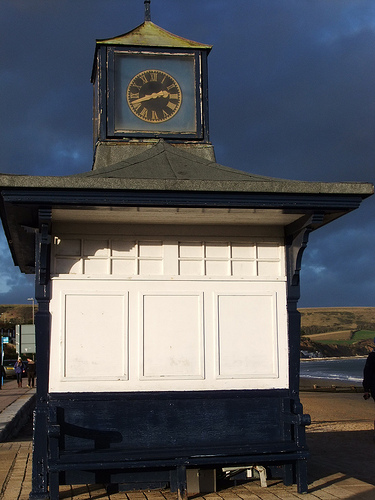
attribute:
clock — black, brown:
[108, 56, 196, 133]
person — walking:
[15, 356, 24, 387]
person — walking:
[25, 356, 37, 390]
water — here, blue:
[301, 353, 374, 383]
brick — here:
[3, 484, 24, 499]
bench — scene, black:
[29, 389, 313, 497]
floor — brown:
[3, 421, 373, 499]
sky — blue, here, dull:
[2, 0, 374, 304]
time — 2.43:
[129, 90, 177, 109]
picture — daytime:
[1, 1, 373, 498]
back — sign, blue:
[14, 323, 38, 357]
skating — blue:
[112, 57, 198, 130]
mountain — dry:
[298, 308, 373, 354]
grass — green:
[1, 303, 37, 324]